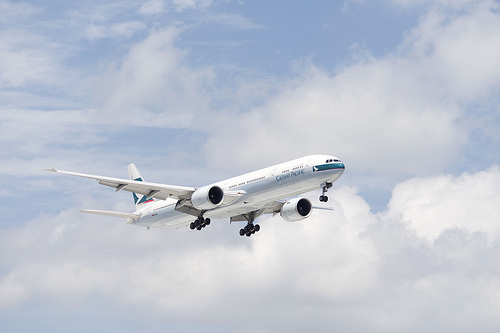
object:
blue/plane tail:
[124, 162, 156, 210]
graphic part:
[275, 174, 285, 183]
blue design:
[133, 175, 144, 182]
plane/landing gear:
[237, 210, 263, 237]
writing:
[275, 169, 305, 182]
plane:
[42, 151, 345, 235]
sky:
[2, 1, 499, 333]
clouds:
[0, 0, 219, 178]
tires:
[239, 229, 245, 237]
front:
[309, 151, 346, 181]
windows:
[325, 159, 330, 164]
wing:
[311, 206, 334, 211]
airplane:
[40, 153, 345, 239]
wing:
[39, 167, 198, 200]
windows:
[329, 159, 333, 163]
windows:
[243, 181, 246, 185]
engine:
[189, 184, 226, 210]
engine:
[277, 197, 313, 223]